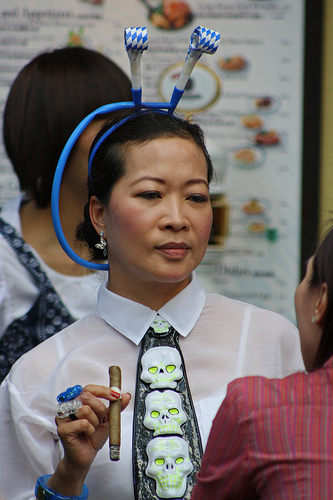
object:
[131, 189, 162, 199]
eye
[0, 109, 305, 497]
woman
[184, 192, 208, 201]
eye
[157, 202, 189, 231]
nose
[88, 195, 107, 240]
ear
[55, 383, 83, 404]
ring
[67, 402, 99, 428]
finger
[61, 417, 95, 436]
finger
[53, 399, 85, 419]
ring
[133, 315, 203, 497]
tie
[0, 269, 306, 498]
shirt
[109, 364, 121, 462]
cigar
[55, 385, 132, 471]
hand